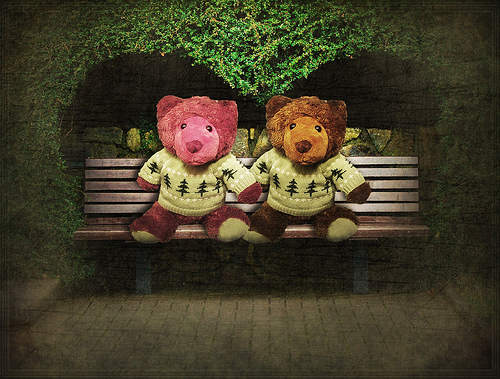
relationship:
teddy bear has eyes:
[125, 93, 262, 248] [176, 121, 216, 135]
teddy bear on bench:
[125, 93, 262, 248] [70, 160, 423, 247]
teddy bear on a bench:
[125, 93, 262, 248] [70, 160, 423, 247]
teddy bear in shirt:
[125, 93, 262, 248] [141, 151, 361, 212]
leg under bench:
[123, 246, 373, 301] [70, 160, 423, 247]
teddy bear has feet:
[125, 93, 262, 248] [137, 215, 365, 243]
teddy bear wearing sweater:
[125, 93, 262, 248] [138, 141, 253, 212]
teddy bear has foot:
[125, 93, 262, 248] [207, 209, 247, 240]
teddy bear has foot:
[125, 93, 262, 248] [126, 228, 158, 248]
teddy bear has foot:
[125, 93, 262, 248] [244, 223, 269, 247]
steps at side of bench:
[1, 226, 82, 344] [70, 160, 423, 247]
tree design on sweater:
[146, 163, 236, 195] [138, 141, 253, 212]